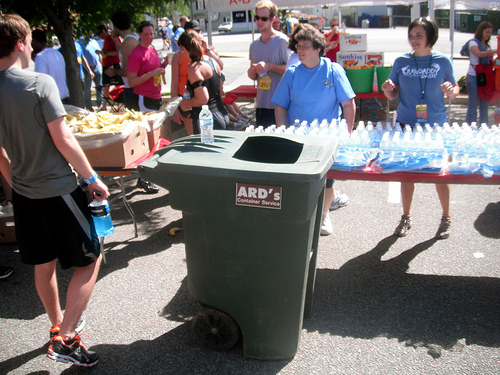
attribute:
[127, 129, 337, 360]
bin — large, plastic, green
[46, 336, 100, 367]
shoe — orange, black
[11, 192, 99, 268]
shorts — black, grey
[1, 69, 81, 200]
shirt — gray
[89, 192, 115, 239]
bottle — blue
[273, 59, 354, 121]
shirt — blue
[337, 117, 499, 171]
bottles — packaged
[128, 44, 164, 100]
shirt — pink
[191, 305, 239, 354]
wheel — black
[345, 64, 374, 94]
pail — green, large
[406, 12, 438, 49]
her hair — short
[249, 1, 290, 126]
people — standing